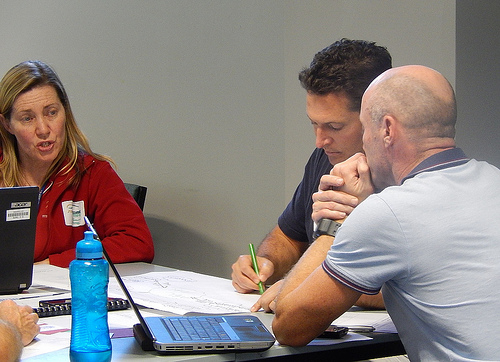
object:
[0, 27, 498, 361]
people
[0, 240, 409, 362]
table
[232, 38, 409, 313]
man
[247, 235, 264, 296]
pen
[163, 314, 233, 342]
keys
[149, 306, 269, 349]
keyboard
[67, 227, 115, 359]
water bottle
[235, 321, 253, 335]
touchpad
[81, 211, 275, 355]
laptop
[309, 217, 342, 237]
watch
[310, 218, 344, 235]
wrist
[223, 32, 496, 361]
man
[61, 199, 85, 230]
name tag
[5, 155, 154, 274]
sweatshirt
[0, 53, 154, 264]
woman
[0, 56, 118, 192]
hair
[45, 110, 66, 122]
left eye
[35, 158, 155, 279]
left arm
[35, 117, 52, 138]
nose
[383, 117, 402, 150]
left ear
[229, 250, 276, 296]
hand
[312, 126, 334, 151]
nose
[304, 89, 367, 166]
face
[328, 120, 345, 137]
left eye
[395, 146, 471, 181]
collar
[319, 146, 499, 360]
shirt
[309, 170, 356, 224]
right hand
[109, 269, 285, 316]
notes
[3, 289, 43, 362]
arm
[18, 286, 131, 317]
spiral notebook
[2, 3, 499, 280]
wall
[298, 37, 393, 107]
hair